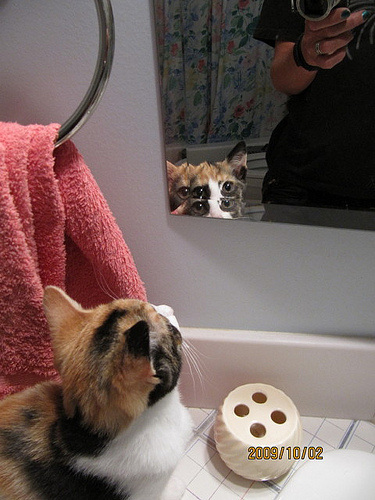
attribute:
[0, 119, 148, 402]
towel — red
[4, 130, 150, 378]
towel — red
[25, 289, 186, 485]
cat — one, observant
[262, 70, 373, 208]
black shirt — black 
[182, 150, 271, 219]
cat — one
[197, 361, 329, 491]
holder — toothbrush, one